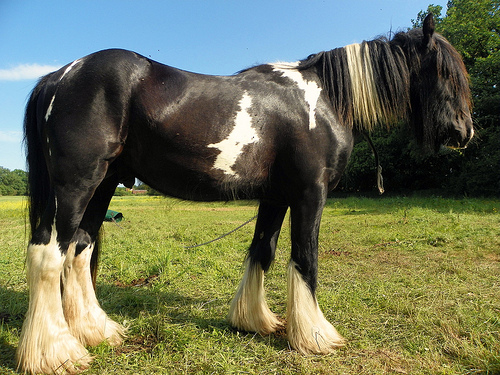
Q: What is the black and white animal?
A: A horse.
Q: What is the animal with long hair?
A: A horse.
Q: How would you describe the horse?
A: Black and white with long hair.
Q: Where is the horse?
A: Field.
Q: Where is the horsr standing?
A: Field.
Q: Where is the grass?
A: Field.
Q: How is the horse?
A: Standing.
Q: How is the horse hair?
A: Long.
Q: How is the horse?
A: Black and white.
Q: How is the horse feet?
A: Hairy.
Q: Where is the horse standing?
A: The outside.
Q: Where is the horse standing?
A: On grass.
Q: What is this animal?
A: Horse.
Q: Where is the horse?
A: In a field.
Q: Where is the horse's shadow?
A: On the grass.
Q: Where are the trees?
A: On the edge of the field.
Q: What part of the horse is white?
A: Feet.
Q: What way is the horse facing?
A: Right.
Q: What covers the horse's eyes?
A: Hair.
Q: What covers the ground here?
A: Grass.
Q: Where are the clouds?
A: In the sky.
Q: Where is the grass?
A: Below the horse.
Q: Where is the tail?
A: On the hind end.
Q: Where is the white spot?
A: The belly.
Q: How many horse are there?
A: One.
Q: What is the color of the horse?
A: Black and white.